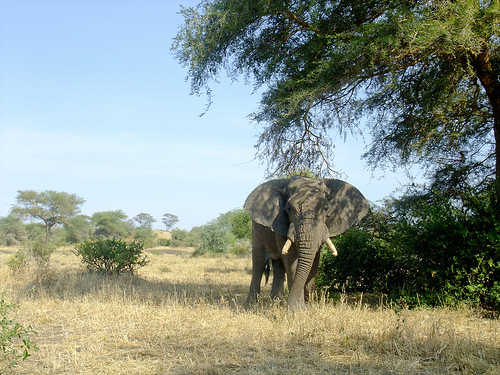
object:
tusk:
[279, 233, 293, 256]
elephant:
[243, 173, 372, 308]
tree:
[11, 189, 87, 245]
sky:
[0, 0, 499, 244]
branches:
[249, 16, 453, 179]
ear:
[244, 180, 288, 235]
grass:
[0, 227, 499, 375]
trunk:
[284, 229, 323, 309]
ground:
[0, 200, 498, 375]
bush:
[313, 179, 499, 314]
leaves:
[72, 236, 75, 240]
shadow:
[19, 265, 249, 302]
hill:
[65, 208, 138, 236]